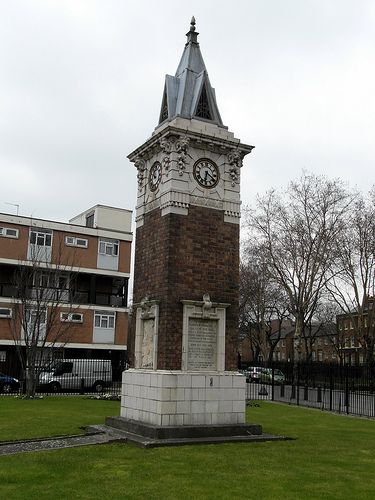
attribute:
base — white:
[118, 370, 239, 425]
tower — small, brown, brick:
[121, 16, 248, 424]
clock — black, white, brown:
[192, 159, 223, 187]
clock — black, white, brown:
[147, 161, 166, 192]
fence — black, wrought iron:
[245, 335, 375, 418]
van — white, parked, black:
[51, 355, 114, 393]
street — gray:
[5, 367, 122, 398]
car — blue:
[5, 368, 23, 392]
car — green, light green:
[259, 366, 287, 387]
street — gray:
[249, 381, 373, 424]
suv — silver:
[249, 363, 261, 377]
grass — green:
[3, 389, 374, 499]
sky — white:
[1, 0, 372, 294]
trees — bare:
[243, 175, 369, 372]